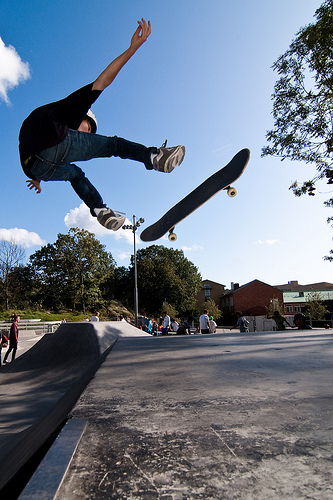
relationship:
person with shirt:
[157, 314, 165, 335] [158, 317, 165, 327]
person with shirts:
[157, 314, 165, 335] [200, 308, 212, 337]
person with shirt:
[3, 312, 20, 365] [10, 322, 20, 342]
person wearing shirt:
[198, 310, 211, 334] [200, 315, 210, 331]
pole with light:
[133, 213, 141, 321] [138, 217, 148, 224]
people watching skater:
[89, 310, 221, 337] [19, 19, 186, 231]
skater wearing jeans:
[19, 19, 186, 231] [22, 130, 161, 218]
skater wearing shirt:
[19, 19, 186, 231] [17, 82, 101, 159]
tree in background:
[26, 227, 116, 311] [2, 225, 332, 343]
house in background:
[197, 280, 245, 302] [2, 225, 332, 343]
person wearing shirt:
[157, 314, 165, 335] [158, 317, 165, 327]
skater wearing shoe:
[19, 19, 186, 231] [153, 141, 187, 174]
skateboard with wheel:
[141, 147, 251, 243] [167, 232, 179, 243]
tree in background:
[128, 244, 200, 317] [2, 225, 332, 343]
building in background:
[280, 280, 330, 327] [2, 225, 332, 343]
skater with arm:
[19, 19, 186, 231] [80, 17, 154, 116]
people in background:
[89, 310, 221, 337] [2, 225, 332, 343]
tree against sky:
[260, 1, 333, 225] [2, 0, 332, 286]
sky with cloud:
[2, 0, 332, 286] [0, 38, 32, 102]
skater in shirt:
[19, 19, 186, 231] [17, 82, 101, 159]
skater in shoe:
[19, 19, 186, 231] [153, 141, 187, 174]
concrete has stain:
[55, 336, 332, 500] [55, 397, 327, 499]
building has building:
[231, 277, 276, 324] [231, 277, 276, 324]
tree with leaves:
[26, 227, 116, 311] [32, 227, 113, 316]